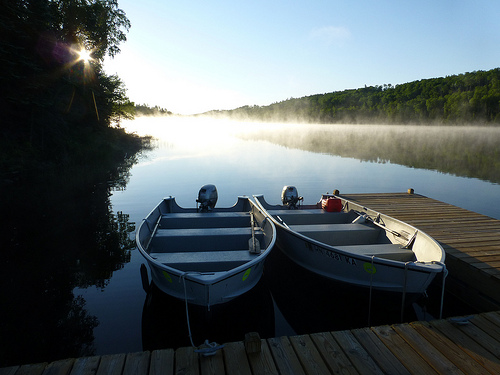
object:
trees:
[2, 136, 155, 349]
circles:
[242, 268, 252, 281]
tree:
[481, 95, 498, 126]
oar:
[248, 212, 261, 255]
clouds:
[306, 25, 356, 50]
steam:
[118, 99, 498, 149]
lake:
[0, 114, 499, 363]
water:
[0, 119, 500, 367]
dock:
[0, 187, 500, 375]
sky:
[98, 0, 498, 115]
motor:
[196, 184, 219, 214]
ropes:
[181, 272, 226, 356]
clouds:
[165, 88, 199, 112]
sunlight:
[55, 35, 104, 77]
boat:
[252, 185, 447, 298]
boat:
[136, 184, 279, 313]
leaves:
[92, 22, 101, 28]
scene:
[0, 0, 500, 375]